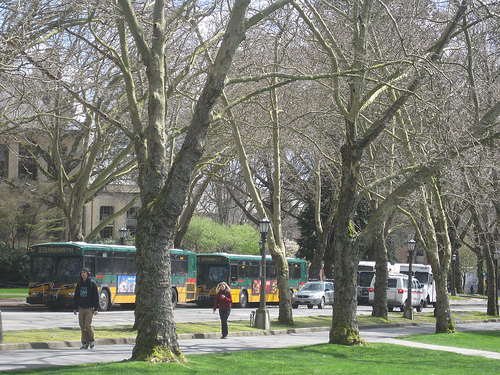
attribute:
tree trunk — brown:
[128, 191, 183, 363]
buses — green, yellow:
[199, 245, 312, 317]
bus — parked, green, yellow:
[24, 240, 196, 310]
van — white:
[330, 245, 426, 315]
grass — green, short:
[297, 349, 419, 370]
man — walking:
[67, 265, 99, 345]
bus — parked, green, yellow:
[204, 252, 305, 300]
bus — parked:
[352, 258, 395, 304]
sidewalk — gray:
[46, 331, 393, 353]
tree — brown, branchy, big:
[295, 22, 409, 344]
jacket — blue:
[76, 279, 98, 309]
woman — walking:
[213, 281, 232, 339]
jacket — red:
[213, 292, 234, 308]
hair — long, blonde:
[213, 279, 235, 292]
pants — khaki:
[75, 304, 97, 345]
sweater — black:
[71, 279, 101, 309]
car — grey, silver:
[295, 281, 336, 304]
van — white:
[371, 273, 426, 308]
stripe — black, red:
[405, 290, 421, 294]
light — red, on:
[397, 288, 404, 297]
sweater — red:
[214, 290, 236, 307]